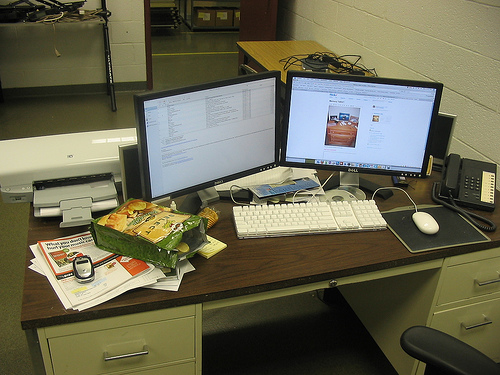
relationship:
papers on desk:
[25, 234, 172, 296] [35, 175, 465, 305]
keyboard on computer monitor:
[232, 197, 390, 240] [270, 67, 444, 180]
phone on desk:
[428, 151, 497, 234] [18, 169, 498, 373]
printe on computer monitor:
[3, 131, 118, 220] [130, 74, 290, 201]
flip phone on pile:
[58, 249, 102, 296] [14, 222, 115, 300]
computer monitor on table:
[281, 67, 443, 177] [237, 40, 382, 92]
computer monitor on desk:
[134, 66, 280, 202] [18, 169, 498, 373]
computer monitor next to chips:
[134, 66, 280, 202] [90, 194, 212, 271]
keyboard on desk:
[232, 197, 390, 240] [18, 169, 498, 373]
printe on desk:
[0, 122, 155, 231] [18, 169, 498, 373]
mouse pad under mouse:
[381, 197, 493, 252] [412, 205, 439, 234]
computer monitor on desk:
[270, 67, 444, 180] [24, 130, 476, 348]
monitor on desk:
[131, 68, 444, 201] [18, 169, 498, 373]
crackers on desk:
[93, 185, 212, 279] [18, 169, 498, 373]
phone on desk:
[64, 250, 92, 287] [24, 184, 494, 366]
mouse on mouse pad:
[411, 209, 441, 238] [378, 204, 491, 256]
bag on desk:
[81, 177, 221, 300] [26, 183, 493, 346]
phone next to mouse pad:
[428, 151, 497, 234] [381, 197, 493, 252]